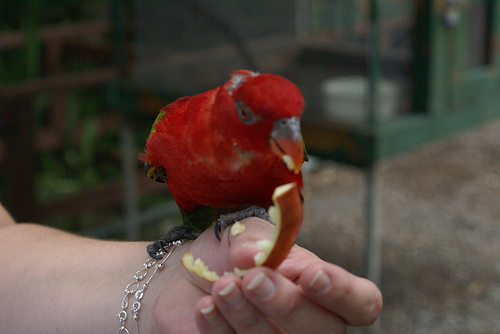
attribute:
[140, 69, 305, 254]
bird — eating, red, feathered, multi-colored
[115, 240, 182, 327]
bracelet — silver linked, silver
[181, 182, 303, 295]
red apple — strip, skinned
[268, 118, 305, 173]
beak — gray, orange, red, black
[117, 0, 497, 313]
bird cage — green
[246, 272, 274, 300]
fingernail — polished, manicured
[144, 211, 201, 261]
claw foot — black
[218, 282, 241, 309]
fingernail — polished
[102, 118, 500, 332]
ground — mulched